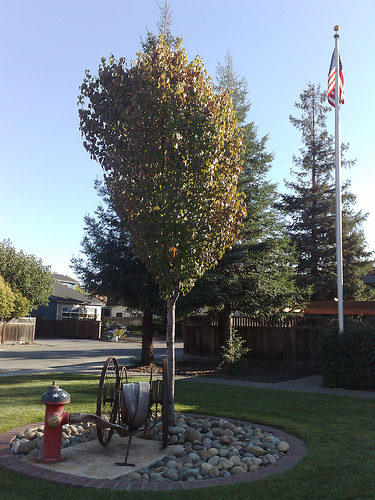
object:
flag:
[327, 48, 345, 109]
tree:
[76, 32, 251, 429]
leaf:
[100, 56, 108, 64]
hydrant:
[40, 379, 71, 462]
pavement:
[2, 338, 375, 400]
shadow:
[1, 346, 182, 361]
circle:
[2, 408, 309, 493]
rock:
[278, 442, 290, 454]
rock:
[219, 433, 235, 447]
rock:
[16, 439, 39, 453]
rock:
[183, 424, 202, 445]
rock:
[218, 447, 230, 457]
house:
[34, 273, 105, 320]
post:
[333, 24, 345, 334]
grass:
[0, 370, 375, 498]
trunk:
[141, 309, 157, 366]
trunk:
[217, 302, 235, 372]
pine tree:
[273, 80, 373, 301]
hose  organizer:
[97, 356, 170, 467]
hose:
[71, 382, 152, 437]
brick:
[207, 476, 222, 489]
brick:
[156, 482, 172, 492]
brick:
[41, 468, 62, 480]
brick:
[128, 480, 146, 492]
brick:
[85, 475, 110, 490]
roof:
[49, 273, 104, 307]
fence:
[183, 314, 372, 372]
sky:
[2, 2, 374, 286]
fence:
[0, 314, 36, 346]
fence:
[34, 318, 101, 341]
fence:
[102, 317, 166, 326]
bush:
[320, 319, 373, 391]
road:
[0, 345, 186, 361]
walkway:
[108, 363, 374, 398]